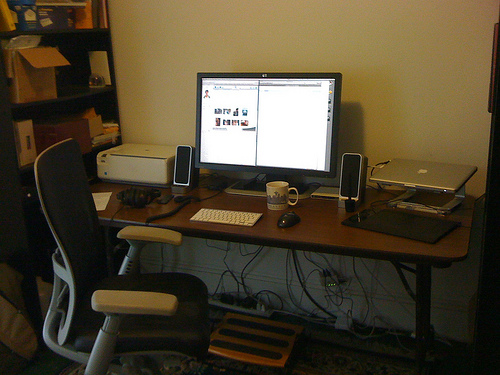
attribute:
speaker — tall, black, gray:
[336, 152, 366, 213]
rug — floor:
[212, 299, 481, 372]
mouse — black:
[273, 205, 300, 224]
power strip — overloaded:
[204, 283, 286, 315]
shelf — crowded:
[6, 10, 133, 288]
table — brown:
[91, 172, 474, 373]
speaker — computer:
[171, 129, 201, 203]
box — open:
[0, 30, 80, 135]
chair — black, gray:
[20, 145, 194, 375]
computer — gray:
[380, 135, 473, 202]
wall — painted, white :
[98, 53, 486, 129]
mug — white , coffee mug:
[264, 178, 300, 208]